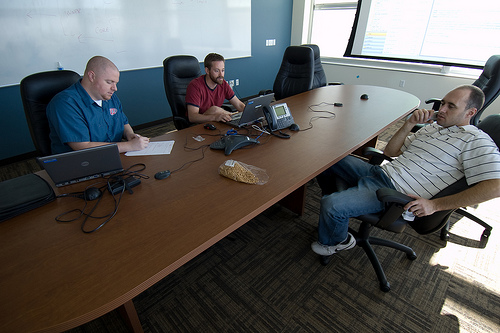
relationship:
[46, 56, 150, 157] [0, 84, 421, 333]
person at table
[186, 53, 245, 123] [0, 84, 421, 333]
person at table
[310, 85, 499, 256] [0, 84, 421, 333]
person at table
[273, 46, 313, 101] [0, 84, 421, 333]
chair at table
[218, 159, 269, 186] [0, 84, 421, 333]
bag on table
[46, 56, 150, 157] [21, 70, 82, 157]
person on chair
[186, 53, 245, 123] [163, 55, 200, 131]
person on chair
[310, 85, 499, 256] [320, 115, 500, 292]
person on chair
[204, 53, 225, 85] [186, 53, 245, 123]
head of person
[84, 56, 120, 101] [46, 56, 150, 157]
head of person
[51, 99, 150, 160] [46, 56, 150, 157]
arm of person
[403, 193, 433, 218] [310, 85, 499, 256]
hand of person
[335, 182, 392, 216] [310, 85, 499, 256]
thigh of person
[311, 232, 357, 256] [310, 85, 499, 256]
foot of person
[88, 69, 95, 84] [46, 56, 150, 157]
ear of person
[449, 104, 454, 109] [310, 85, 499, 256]
eye of person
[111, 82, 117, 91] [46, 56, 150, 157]
nose of person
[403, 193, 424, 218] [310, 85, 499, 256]
fingers of person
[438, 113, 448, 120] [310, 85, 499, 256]
mouth of person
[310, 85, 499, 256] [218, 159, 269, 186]
person focused on bag